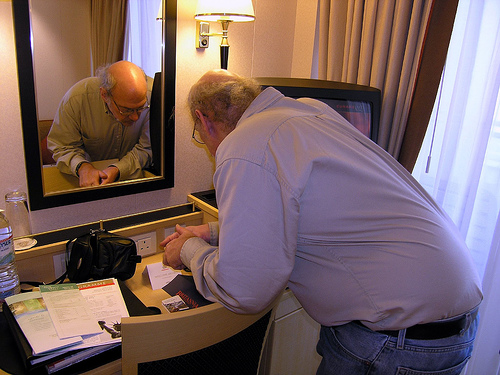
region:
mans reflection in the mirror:
[50, 47, 162, 189]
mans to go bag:
[47, 217, 177, 307]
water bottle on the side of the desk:
[0, 207, 29, 302]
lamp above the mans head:
[187, 5, 256, 70]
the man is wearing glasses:
[184, 110, 214, 146]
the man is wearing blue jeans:
[315, 280, 482, 372]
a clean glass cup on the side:
[2, 183, 44, 258]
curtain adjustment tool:
[420, 48, 449, 177]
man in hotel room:
[139, 58, 485, 373]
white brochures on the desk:
[5, 275, 140, 368]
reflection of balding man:
[47, 59, 154, 186]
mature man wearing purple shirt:
[165, 67, 482, 373]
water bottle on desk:
[0, 207, 21, 298]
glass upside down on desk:
[3, 188, 34, 248]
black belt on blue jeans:
[319, 301, 477, 372]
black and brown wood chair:
[123, 285, 285, 373]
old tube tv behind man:
[252, 76, 379, 141]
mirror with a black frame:
[11, 1, 176, 206]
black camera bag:
[66, 228, 136, 278]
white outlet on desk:
[126, 235, 159, 255]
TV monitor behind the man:
[253, 73, 381, 143]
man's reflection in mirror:
[48, 54, 162, 186]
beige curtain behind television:
[268, 0, 458, 373]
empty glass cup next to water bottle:
[0, 191, 41, 296]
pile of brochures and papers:
[9, 273, 133, 360]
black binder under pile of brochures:
[6, 269, 155, 374]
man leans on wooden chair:
[121, 76, 482, 373]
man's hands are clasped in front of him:
[149, 218, 222, 278]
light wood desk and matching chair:
[0, 195, 344, 374]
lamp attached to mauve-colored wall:
[190, 0, 260, 85]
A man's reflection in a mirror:
[7, 3, 185, 210]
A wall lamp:
[185, 1, 261, 91]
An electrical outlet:
[124, 223, 163, 260]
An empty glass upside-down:
[3, 181, 43, 259]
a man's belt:
[310, 292, 485, 343]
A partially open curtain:
[302, 0, 493, 360]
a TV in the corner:
[227, 67, 392, 194]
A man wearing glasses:
[45, 51, 155, 176]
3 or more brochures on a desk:
[2, 270, 138, 365]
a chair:
[110, 276, 293, 370]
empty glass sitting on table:
[6, 190, 45, 247]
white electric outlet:
[129, 223, 164, 257]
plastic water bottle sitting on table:
[0, 208, 25, 293]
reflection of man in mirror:
[47, 54, 165, 187]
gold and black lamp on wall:
[186, 0, 257, 70]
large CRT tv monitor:
[332, 83, 387, 144]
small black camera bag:
[55, 219, 146, 287]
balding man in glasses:
[180, 62, 275, 187]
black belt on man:
[407, 316, 464, 345]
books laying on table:
[13, 267, 134, 373]